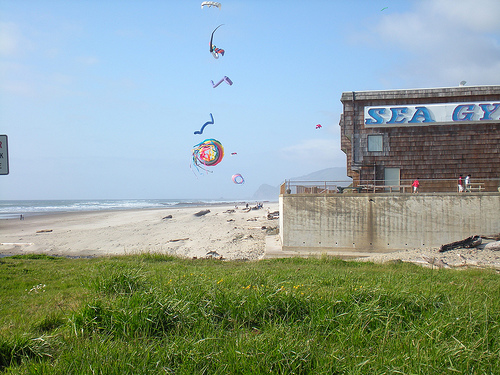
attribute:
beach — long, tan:
[7, 197, 283, 259]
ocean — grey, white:
[4, 193, 265, 211]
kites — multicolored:
[183, 2, 331, 195]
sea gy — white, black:
[355, 99, 499, 133]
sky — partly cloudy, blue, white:
[3, 1, 494, 100]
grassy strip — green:
[1, 252, 500, 372]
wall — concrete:
[276, 188, 495, 254]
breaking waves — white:
[3, 197, 168, 214]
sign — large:
[451, 95, 500, 128]